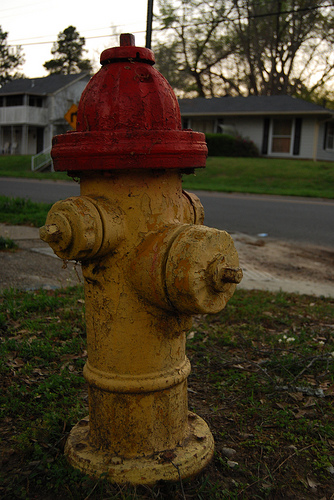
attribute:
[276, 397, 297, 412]
leaf — dead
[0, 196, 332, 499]
ground — pebbly, grassy, dirt, leafy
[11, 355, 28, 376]
leaf — dead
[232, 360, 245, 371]
leaf — dead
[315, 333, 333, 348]
leaf — dead, brown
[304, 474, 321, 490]
leaf — dead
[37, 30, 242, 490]
fire hydrant — yellow, peeling paint, red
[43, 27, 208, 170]
top — painted red, red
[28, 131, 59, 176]
hand rail — white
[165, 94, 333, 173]
house — white, single story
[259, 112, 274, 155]
shutter — black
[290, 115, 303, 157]
shutter — black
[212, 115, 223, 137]
shutter — black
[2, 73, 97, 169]
house — two story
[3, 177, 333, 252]
roadway — paved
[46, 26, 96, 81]
tree — in the distance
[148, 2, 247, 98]
tree — in distance, in the distance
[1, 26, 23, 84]
tree — in distance, in the distance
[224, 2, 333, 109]
tree — in distance, in the distance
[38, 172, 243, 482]
bottom portion — yellow, for hose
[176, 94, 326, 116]
roof — black, shingled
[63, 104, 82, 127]
traffic sign — yellow, black